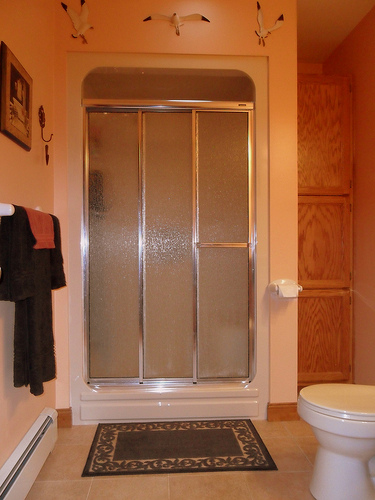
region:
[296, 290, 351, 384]
wooden cabinet below wooden cabinet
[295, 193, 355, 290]
wooden cabinet below wooden cabinet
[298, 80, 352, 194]
wooden cabinet above wooden cabinet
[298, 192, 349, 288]
wooden cabinet above wooden cabinet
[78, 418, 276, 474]
rug in front of shower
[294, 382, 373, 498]
toilet next to wooden cabinet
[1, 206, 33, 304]
black towel hanging on rack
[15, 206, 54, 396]
black towel hanging on rack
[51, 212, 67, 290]
black towel hanging on rack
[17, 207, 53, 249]
red towel hanging on rack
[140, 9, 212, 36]
a wall decoration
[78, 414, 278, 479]
a large bath mat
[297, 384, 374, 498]
part of a white toilet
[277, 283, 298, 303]
a roll of tissue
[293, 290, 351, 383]
a brown cabinet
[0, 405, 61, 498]
part of a wall heater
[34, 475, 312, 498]
part of a tile floor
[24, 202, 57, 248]
a pink washcloth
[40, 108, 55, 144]
a wall hook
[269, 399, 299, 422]
part of a brown wall trim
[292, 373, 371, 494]
this is a toilet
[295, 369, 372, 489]
this is a white toilet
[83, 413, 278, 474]
this is a mat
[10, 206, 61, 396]
this is a towel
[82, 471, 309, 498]
these are tiles on the floor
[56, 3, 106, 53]
this is a bird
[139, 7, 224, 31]
this is a bird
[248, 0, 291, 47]
this is a bird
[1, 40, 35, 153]
this is a picture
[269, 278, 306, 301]
this is a toilet paper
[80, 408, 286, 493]
the green and beige mat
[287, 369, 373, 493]
the white ceramic toilet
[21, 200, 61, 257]
the pink wash cloth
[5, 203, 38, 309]
the black hand towel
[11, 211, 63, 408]
the black bath towel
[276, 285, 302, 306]
the white toilet tissue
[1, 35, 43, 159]
the picture on the wall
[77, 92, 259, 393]
the framed shower doors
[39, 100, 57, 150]
the decorative hook on the wall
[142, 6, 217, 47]
the middle bird on the wall